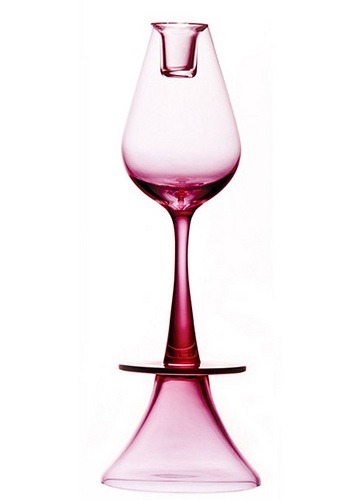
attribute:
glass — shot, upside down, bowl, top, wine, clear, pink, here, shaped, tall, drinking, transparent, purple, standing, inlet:
[104, 13, 351, 340]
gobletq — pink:
[119, 109, 253, 219]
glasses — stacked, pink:
[94, 13, 293, 491]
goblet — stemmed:
[88, 130, 309, 419]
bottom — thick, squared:
[122, 383, 221, 484]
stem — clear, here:
[155, 210, 230, 287]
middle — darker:
[138, 246, 229, 352]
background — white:
[1, 171, 141, 313]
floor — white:
[50, 457, 125, 497]